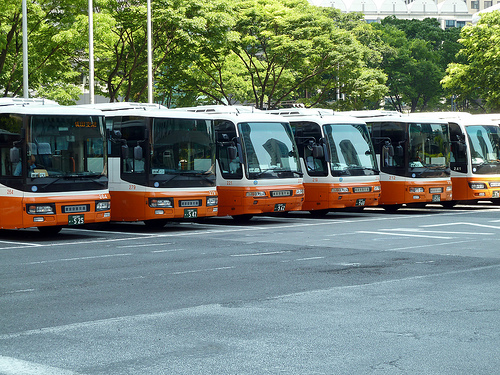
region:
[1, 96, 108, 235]
an orange and white parked bus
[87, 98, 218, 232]
an orange and white parked bus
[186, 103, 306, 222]
an orange and white parked bus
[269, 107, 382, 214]
an orange and white parked bus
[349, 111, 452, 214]
an orange and white parked bus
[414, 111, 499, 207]
an orange and white parked bus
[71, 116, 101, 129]
electronic bus destination sign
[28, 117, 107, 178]
a bus front windshield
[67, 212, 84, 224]
a bus license plate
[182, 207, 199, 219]
a bus license plate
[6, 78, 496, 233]
fleet of buses in a row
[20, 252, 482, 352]
lot with buses on it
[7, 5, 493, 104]
tree tops behind buses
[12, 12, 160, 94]
poles behind the buses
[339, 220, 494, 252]
white marks on the concrete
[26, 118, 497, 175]
front windows of buses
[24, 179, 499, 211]
lights on front of buses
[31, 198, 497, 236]
tires on the buses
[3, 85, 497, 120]
units on top of buses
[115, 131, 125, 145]
mirror on the bus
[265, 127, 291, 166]
part of a window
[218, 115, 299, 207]
this is a bas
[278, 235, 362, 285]
this is the road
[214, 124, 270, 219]
the buses are parked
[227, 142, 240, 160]
this is a mirror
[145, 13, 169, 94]
this is a pole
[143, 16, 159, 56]
the pole is white in color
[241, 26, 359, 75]
this is a tree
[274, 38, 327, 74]
the leaves are green in color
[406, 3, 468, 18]
this is a wall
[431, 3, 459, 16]
the wall is white in color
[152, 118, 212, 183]
a bus front windshield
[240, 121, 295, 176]
a bus front windshield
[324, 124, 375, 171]
a bus front windshield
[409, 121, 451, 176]
a bus front windshield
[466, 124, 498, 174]
a bus front windshield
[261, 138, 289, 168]
reflection of a tall building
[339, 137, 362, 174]
reflection of a tall building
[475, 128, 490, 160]
reflection of a tall building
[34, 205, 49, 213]
a bus front headlight